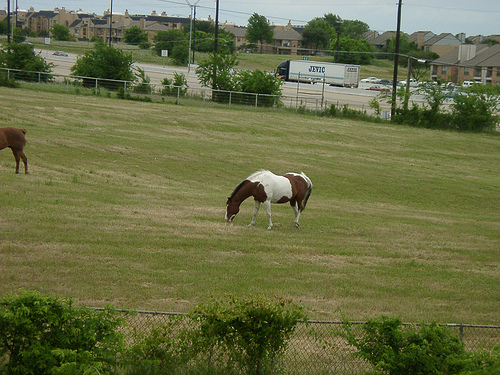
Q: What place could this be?
A: It is a field.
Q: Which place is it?
A: It is a field.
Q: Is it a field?
A: Yes, it is a field.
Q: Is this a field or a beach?
A: It is a field.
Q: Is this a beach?
A: No, it is a field.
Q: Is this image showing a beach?
A: No, the picture is showing a field.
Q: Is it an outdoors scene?
A: Yes, it is outdoors.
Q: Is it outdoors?
A: Yes, it is outdoors.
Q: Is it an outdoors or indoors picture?
A: It is outdoors.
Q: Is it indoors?
A: No, it is outdoors.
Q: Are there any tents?
A: No, there are no tents.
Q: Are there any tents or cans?
A: No, there are no tents or cans.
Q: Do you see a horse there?
A: Yes, there is a horse.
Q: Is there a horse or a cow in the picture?
A: Yes, there is a horse.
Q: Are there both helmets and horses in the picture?
A: No, there is a horse but no helmets.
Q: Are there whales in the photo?
A: No, there are no whales.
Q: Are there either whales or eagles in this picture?
A: No, there are no whales or eagles.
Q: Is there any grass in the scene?
A: Yes, there is grass.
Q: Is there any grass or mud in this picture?
A: Yes, there is grass.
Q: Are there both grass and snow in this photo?
A: No, there is grass but no snow.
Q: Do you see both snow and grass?
A: No, there is grass but no snow.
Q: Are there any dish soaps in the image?
A: No, there are no dish soaps.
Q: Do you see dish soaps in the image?
A: No, there are no dish soaps.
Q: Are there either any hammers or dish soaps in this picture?
A: No, there are no dish soaps or hammers.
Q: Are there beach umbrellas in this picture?
A: No, there are no beach umbrellas.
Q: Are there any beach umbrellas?
A: No, there are no beach umbrellas.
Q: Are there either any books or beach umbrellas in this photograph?
A: No, there are no beach umbrellas or books.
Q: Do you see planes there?
A: No, there are no planes.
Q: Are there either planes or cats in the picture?
A: No, there are no planes or cats.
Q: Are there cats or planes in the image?
A: No, there are no planes or cats.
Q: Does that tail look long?
A: Yes, the tail is long.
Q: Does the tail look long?
A: Yes, the tail is long.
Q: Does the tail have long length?
A: Yes, the tail is long.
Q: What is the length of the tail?
A: The tail is long.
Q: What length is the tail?
A: The tail is long.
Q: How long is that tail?
A: The tail is long.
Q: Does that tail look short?
A: No, the tail is long.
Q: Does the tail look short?
A: No, the tail is long.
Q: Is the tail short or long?
A: The tail is long.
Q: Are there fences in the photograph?
A: Yes, there is a fence.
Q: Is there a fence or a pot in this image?
A: Yes, there is a fence.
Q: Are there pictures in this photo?
A: No, there are no pictures.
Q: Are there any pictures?
A: No, there are no pictures.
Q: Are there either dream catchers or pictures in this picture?
A: No, there are no pictures or dream catchers.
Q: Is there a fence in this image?
A: Yes, there is a fence.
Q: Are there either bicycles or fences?
A: Yes, there is a fence.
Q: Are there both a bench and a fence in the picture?
A: No, there is a fence but no benches.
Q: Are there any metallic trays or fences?
A: Yes, there is a metal fence.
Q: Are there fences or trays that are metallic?
A: Yes, the fence is metallic.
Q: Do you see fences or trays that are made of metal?
A: Yes, the fence is made of metal.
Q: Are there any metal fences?
A: Yes, there is a metal fence.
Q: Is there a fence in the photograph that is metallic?
A: Yes, there is a fence that is metallic.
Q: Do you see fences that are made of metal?
A: Yes, there is a fence that is made of metal.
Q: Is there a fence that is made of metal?
A: Yes, there is a fence that is made of metal.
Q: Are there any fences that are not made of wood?
A: Yes, there is a fence that is made of metal.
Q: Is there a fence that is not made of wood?
A: Yes, there is a fence that is made of metal.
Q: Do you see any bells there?
A: No, there are no bells.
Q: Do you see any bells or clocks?
A: No, there are no bells or clocks.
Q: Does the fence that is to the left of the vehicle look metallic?
A: Yes, the fence is metallic.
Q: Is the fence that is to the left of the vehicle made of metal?
A: Yes, the fence is made of metal.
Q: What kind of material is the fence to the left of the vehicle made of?
A: The fence is made of metal.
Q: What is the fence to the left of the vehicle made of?
A: The fence is made of metal.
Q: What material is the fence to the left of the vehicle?
A: The fence is made of metal.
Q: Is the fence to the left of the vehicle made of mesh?
A: No, the fence is made of metal.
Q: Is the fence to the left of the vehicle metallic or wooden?
A: The fence is metallic.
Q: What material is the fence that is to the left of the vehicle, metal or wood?
A: The fence is made of metal.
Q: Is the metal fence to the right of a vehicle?
A: No, the fence is to the left of a vehicle.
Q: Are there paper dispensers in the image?
A: No, there are no paper dispensers.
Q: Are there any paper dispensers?
A: No, there are no paper dispensers.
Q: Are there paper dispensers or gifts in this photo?
A: No, there are no paper dispensers or gifts.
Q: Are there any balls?
A: No, there are no balls.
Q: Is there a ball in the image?
A: No, there are no balls.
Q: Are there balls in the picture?
A: No, there are no balls.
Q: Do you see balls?
A: No, there are no balls.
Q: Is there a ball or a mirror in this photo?
A: No, there are no balls or mirrors.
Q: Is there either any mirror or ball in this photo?
A: No, there are no balls or mirrors.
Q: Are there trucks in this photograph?
A: Yes, there is a truck.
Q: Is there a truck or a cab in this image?
A: Yes, there is a truck.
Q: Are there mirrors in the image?
A: No, there are no mirrors.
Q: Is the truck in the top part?
A: Yes, the truck is in the top of the image.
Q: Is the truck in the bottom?
A: No, the truck is in the top of the image.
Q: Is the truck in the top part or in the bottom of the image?
A: The truck is in the top of the image.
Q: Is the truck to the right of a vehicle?
A: No, the truck is to the left of a vehicle.